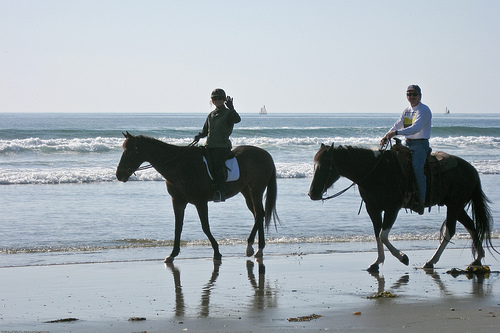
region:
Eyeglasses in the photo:
[212, 84, 223, 107]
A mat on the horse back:
[227, 150, 240, 192]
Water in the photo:
[29, 103, 83, 131]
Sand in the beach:
[98, 305, 170, 330]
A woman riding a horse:
[190, 76, 241, 193]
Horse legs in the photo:
[155, 244, 235, 272]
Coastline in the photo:
[44, 223, 176, 267]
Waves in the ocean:
[5, 122, 95, 187]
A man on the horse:
[377, 63, 441, 208]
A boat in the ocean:
[258, 96, 273, 119]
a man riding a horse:
[306, 80, 497, 279]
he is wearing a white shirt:
[387, 104, 436, 146]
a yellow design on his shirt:
[399, 114, 419, 131]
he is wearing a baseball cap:
[400, 80, 427, 92]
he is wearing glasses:
[405, 88, 422, 102]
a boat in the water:
[253, 102, 272, 118]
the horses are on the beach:
[2, 85, 492, 331]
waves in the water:
[0, 127, 497, 192]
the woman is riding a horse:
[107, 87, 282, 272]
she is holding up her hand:
[193, 78, 243, 210]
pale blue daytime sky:
[2, 2, 498, 112]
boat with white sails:
[256, 102, 268, 115]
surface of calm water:
[0, 112, 498, 124]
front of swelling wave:
[0, 126, 499, 141]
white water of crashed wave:
[0, 135, 498, 152]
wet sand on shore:
[3, 269, 498, 330]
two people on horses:
[116, 83, 497, 272]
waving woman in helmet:
[197, 86, 240, 145]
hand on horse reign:
[185, 133, 204, 148]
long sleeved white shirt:
[391, 103, 433, 144]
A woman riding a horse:
[191, 87, 241, 205]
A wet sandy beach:
[3, 235, 499, 331]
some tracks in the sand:
[39, 286, 392, 329]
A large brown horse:
[114, 131, 282, 263]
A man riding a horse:
[378, 85, 435, 217]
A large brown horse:
[306, 142, 498, 275]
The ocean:
[0, 111, 497, 248]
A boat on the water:
[442, 105, 452, 117]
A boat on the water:
[258, 103, 268, 115]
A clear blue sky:
[0, 0, 498, 112]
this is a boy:
[199, 87, 246, 167]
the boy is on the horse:
[182, 82, 239, 194]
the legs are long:
[162, 208, 219, 267]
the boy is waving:
[223, 92, 242, 119]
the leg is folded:
[376, 224, 410, 266]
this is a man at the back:
[388, 77, 433, 184]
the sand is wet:
[229, 258, 296, 311]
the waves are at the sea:
[58, 129, 104, 159]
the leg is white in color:
[381, 233, 398, 263]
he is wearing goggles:
[405, 89, 420, 97]